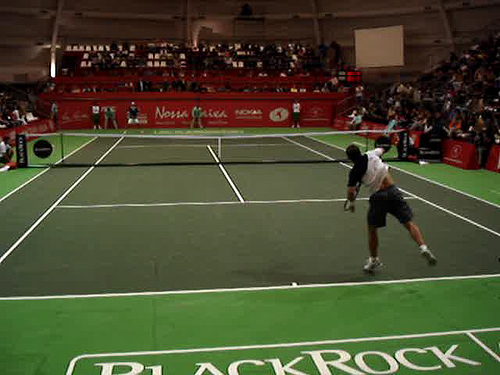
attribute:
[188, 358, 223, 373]
letter — white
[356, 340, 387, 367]
letter — white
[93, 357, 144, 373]
letter — white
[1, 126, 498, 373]
pitch — green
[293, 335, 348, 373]
letter — white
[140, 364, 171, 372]
letter — white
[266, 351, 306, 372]
letter — white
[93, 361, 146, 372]
letter — white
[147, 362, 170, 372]
letter — white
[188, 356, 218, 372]
letter — white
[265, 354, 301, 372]
letter — white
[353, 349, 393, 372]
letter — white